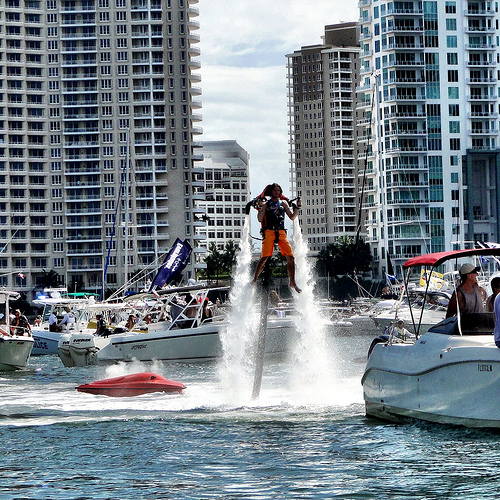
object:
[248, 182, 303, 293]
skier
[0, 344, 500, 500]
water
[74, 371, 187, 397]
jet ski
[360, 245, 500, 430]
boat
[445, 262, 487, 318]
man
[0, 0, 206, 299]
buildings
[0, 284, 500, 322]
shore line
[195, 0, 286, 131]
clouds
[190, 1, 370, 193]
sky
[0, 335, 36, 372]
boats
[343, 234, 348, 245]
leaves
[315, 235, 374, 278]
tree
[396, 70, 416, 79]
window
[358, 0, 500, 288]
building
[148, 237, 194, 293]
banner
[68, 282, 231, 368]
boat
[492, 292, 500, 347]
people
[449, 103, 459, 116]
windows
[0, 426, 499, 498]
ripples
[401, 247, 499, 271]
hood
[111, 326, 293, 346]
stripes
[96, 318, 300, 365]
boat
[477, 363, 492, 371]
lettering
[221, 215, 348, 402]
water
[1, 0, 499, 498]
background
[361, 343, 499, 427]
side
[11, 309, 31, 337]
person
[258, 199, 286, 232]
jet pack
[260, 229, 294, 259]
shorts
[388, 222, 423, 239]
balconies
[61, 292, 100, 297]
roof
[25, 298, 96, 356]
boat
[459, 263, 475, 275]
hat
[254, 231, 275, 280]
legs